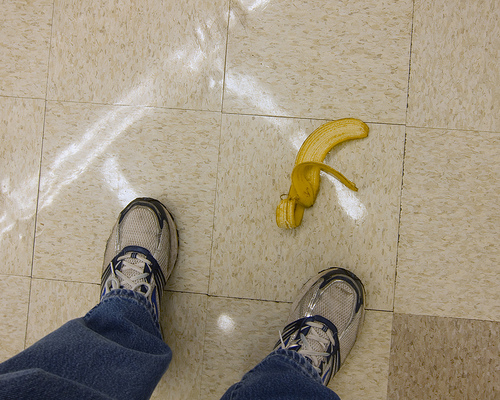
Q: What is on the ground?
A: A banana peel.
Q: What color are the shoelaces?
A: White.